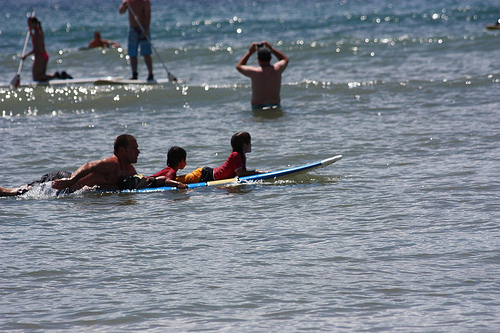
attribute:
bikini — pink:
[29, 28, 52, 63]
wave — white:
[0, 75, 499, 115]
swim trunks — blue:
[127, 25, 153, 63]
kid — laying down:
[170, 132, 264, 186]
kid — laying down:
[146, 144, 186, 184]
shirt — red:
[208, 152, 261, 187]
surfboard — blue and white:
[62, 148, 344, 195]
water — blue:
[340, 193, 499, 293]